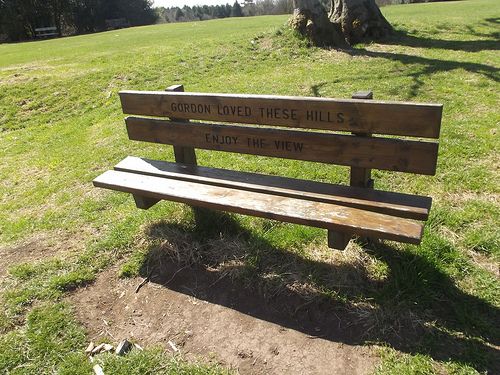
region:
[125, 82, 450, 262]
The bench is made out of wood.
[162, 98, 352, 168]
The writing on the bench is black.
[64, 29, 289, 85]
The grass is freshly cut.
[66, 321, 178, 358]
Rocks on the ground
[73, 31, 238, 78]
The grass is green.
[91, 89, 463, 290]
A bench is sitting in the park.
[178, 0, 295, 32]
Trees are in the background.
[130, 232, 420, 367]
The area is full with dirt.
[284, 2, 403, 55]
A tree stump behind the bench.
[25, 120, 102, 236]
Part of the grass is dry.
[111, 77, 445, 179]
brown bench with inscription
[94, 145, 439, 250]
brown seat of bench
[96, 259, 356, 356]
brown dirt by bench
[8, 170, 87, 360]
green and brown grass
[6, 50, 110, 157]
green and brown grass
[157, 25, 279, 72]
green and brown grass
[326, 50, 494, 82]
green and brown grass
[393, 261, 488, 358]
green and brown grass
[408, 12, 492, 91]
green and brown grass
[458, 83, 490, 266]
green and brown grass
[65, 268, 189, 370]
Patch or brown dirt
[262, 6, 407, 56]
Base of tall tree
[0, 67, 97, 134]
Patch of green grass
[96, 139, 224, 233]
Seat portion of park bench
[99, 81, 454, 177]
Back portion of park bench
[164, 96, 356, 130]
Engraved words in wood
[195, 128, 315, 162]
Engraved message in wood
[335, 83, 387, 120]
Metal support for park bench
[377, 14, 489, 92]
Shadow of tree on the ground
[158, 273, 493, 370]
Park bench's shadow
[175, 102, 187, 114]
a letter 'O' written in black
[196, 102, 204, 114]
a letter 'O' written in black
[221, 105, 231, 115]
a letter 'O' written in black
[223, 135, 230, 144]
a letter 'O' written in black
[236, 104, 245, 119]
a letter 'E' written in black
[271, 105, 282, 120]
a letter 'E' written in black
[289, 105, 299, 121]
a letter 'E' written in black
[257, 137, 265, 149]
a letter 'E' written in black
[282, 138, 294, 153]
a letter 'E' written in black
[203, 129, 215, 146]
a letter 'E' written in black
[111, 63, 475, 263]
The bench is wooden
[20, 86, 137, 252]
The grass is green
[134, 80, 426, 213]
The bench has words carved into it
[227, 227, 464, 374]
There is a shadow on the ground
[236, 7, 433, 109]
There is a tree in the back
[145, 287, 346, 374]
The dirt is brown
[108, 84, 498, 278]
No one is on the bench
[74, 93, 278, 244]
The sun is shining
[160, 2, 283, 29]
There are trees in the back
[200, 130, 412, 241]
The bench is brown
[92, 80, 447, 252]
wooden bench over looking the hills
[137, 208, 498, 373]
shadow of a bench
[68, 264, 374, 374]
dirt patch of bench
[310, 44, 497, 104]
shadow of tree behind bench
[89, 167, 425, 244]
wooden slat of bench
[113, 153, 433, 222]
wooden slat of bench